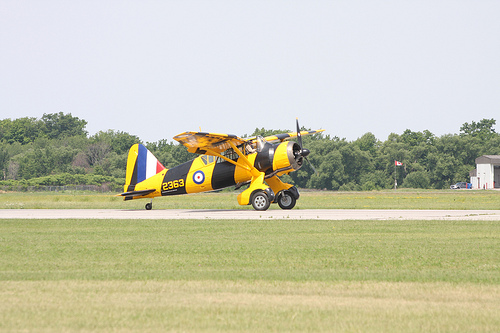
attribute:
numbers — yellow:
[157, 177, 188, 191]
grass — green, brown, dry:
[6, 216, 497, 283]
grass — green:
[15, 227, 499, 329]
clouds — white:
[299, 4, 449, 102]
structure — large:
[468, 150, 499, 190]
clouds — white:
[378, 58, 440, 99]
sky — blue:
[2, 2, 497, 142]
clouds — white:
[258, 26, 391, 98]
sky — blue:
[9, 12, 474, 129]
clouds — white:
[179, 42, 239, 69]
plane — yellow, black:
[105, 117, 327, 213]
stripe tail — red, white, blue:
[125, 142, 165, 182]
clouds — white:
[78, 50, 219, 84]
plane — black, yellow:
[116, 121, 329, 218]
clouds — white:
[327, 19, 481, 112]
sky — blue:
[1, 0, 497, 114]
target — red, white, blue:
[187, 168, 212, 187]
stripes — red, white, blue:
[132, 145, 165, 185]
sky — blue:
[7, 8, 497, 122]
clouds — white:
[222, 41, 466, 86]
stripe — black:
[138, 133, 184, 250]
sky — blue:
[6, 9, 484, 114]